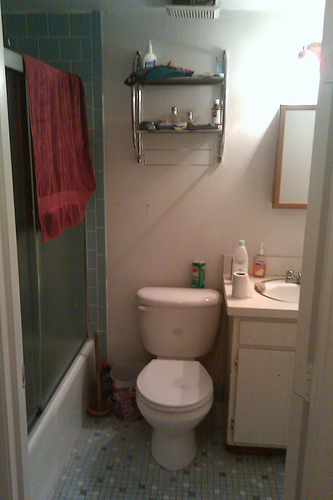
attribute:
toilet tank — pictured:
[133, 284, 222, 359]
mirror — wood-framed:
[259, 99, 322, 214]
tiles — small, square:
[62, 476, 114, 498]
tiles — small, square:
[164, 479, 281, 498]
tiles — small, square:
[200, 449, 279, 488]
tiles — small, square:
[82, 421, 143, 470]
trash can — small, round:
[110, 362, 142, 425]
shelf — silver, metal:
[124, 45, 230, 165]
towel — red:
[13, 52, 96, 240]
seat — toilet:
[120, 279, 229, 437]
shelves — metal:
[137, 55, 225, 162]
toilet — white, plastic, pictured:
[134, 285, 223, 471]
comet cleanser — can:
[189, 260, 206, 288]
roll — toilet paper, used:
[226, 270, 253, 303]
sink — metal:
[253, 276, 298, 303]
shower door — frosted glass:
[12, 59, 102, 418]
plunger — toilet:
[81, 328, 121, 425]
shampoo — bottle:
[251, 241, 267, 278]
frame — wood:
[272, 97, 287, 207]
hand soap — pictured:
[254, 239, 267, 278]